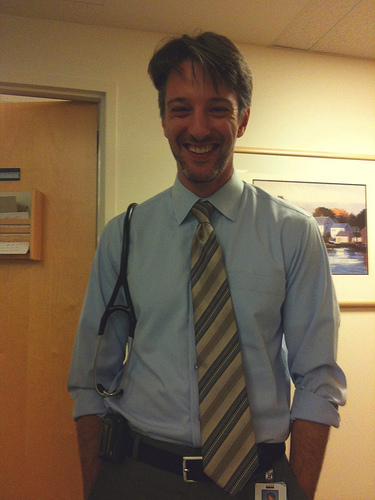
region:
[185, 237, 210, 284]
Blue stripe on a tie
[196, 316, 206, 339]
Blue stripe on a tie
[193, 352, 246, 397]
Blue stripe on a tie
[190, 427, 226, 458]
Blue stripe on a tie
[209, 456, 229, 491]
Grey stripe on a tie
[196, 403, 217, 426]
Grey stripe on a tie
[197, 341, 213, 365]
Grey stripe on a tie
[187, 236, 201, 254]
Grey stripe on a tie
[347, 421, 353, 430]
part of a wall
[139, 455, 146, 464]
part of a belt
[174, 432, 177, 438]
part of a shirt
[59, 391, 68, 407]
part of a door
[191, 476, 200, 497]
part of a short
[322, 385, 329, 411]
part of a shirt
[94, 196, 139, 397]
Stethoscope hanging on a man's shoulder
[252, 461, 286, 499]
Identification card hanging from a belt loop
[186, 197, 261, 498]
Striped tie around a man's neck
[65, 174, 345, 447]
Light blue shirt on a man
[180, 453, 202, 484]
Steel buckle on a belt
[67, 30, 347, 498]
Man in a light blue shirt and brown tie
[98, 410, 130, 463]
Pager on the hip of a man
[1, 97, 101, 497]
A wooden door left ajar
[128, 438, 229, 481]
Leather belt on a man's waist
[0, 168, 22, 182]
Empty nameplate on a wooden door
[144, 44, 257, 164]
face of the person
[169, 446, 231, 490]
belt of the person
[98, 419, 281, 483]
a man wearing belt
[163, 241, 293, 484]
a tie of the person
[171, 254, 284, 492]
a man wearing tie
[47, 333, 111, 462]
hand of the person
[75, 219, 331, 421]
a man wearing shirt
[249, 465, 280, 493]
a man wearing id card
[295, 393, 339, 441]
shirt of the man folded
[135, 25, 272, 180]
head of a person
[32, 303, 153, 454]
arm of a person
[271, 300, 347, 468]
arm of a person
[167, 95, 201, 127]
eye of a person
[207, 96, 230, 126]
eye of a person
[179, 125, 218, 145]
nose of a person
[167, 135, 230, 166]
mouth of a person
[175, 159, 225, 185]
jaw of a person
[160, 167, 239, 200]
neck of a person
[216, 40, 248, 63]
hair of a person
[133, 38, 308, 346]
man wearing a blue shirt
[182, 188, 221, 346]
man wearing a tie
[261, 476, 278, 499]
small card of identification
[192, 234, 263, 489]
gray and blue stripes tie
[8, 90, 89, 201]
open door behind a man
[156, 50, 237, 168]
short graying blond hair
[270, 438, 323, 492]
left hand in the pocket